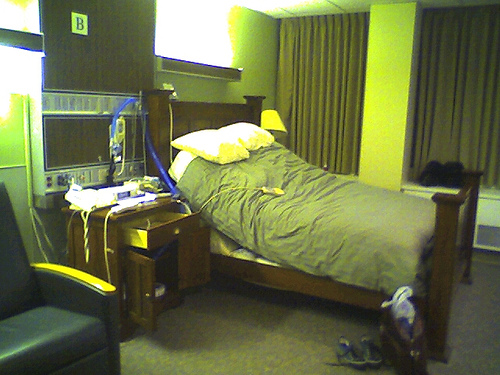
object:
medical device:
[65, 97, 181, 216]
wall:
[31, 1, 159, 188]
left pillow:
[219, 120, 274, 150]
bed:
[142, 86, 484, 365]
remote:
[189, 185, 286, 212]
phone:
[64, 184, 116, 267]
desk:
[63, 180, 215, 342]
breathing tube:
[142, 134, 183, 200]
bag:
[381, 283, 430, 374]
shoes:
[336, 333, 366, 369]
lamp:
[0, 3, 47, 172]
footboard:
[420, 166, 480, 365]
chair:
[0, 179, 122, 374]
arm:
[29, 261, 120, 304]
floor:
[110, 246, 499, 374]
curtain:
[273, 15, 499, 193]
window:
[275, 14, 499, 187]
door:
[121, 247, 162, 333]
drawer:
[120, 210, 199, 253]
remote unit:
[254, 185, 288, 198]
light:
[152, 0, 238, 69]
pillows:
[171, 129, 248, 165]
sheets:
[172, 133, 444, 298]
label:
[67, 5, 92, 37]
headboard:
[140, 75, 265, 188]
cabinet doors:
[120, 208, 209, 335]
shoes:
[418, 157, 443, 186]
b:
[71, 13, 86, 36]